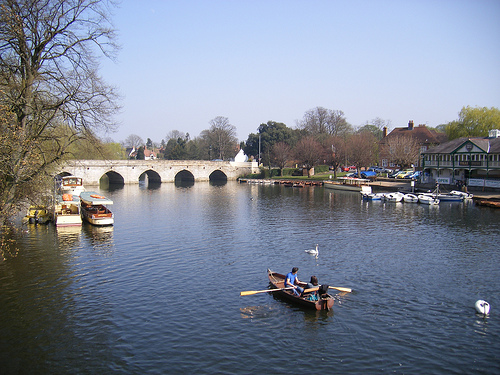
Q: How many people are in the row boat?
A: Two.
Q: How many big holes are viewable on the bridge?
A: Five.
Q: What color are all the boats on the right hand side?
A: White.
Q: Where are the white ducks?
A: Right side of row boat.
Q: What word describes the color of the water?
A: Dark.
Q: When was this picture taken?
A: Daytime.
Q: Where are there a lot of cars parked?
A: In front of building on right.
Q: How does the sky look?
A: Clear.